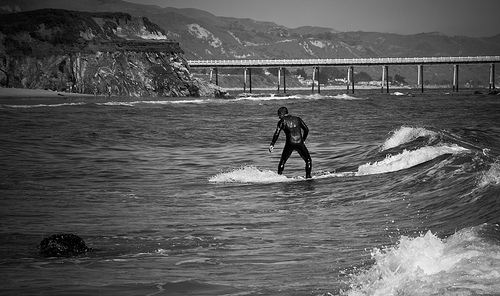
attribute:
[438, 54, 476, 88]
pillar — strong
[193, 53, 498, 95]
bridge — long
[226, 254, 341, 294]
ripples — Small 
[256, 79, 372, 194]
person — surfing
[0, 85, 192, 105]
beach — rocky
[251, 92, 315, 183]
surfer — standing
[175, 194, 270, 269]
water — white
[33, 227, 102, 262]
rock — small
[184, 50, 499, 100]
bridge — Tall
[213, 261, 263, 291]
ripples — Small 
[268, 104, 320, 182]
man — surfiing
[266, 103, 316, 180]
surfer — surfing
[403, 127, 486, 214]
wave — small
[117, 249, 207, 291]
ripples — Small 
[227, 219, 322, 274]
ripples — small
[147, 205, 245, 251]
ripples — small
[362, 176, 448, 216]
ripples — small